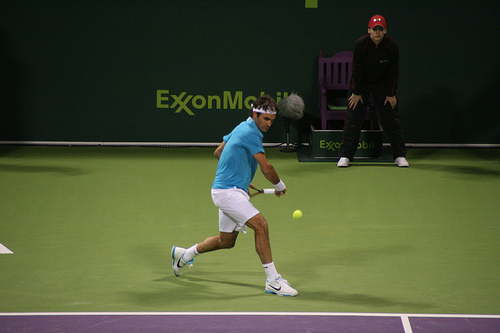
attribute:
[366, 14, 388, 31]
cap — red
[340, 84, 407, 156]
pants — dark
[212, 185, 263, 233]
shorts — white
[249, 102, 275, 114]
headband — white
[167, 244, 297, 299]
shoes — white, nike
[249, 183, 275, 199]
racket — swung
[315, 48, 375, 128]
chair — purple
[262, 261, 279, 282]
socks — white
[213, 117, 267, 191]
shirt — blue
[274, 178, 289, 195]
wristband — white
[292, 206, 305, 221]
ball — round, yellow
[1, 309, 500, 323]
line — white